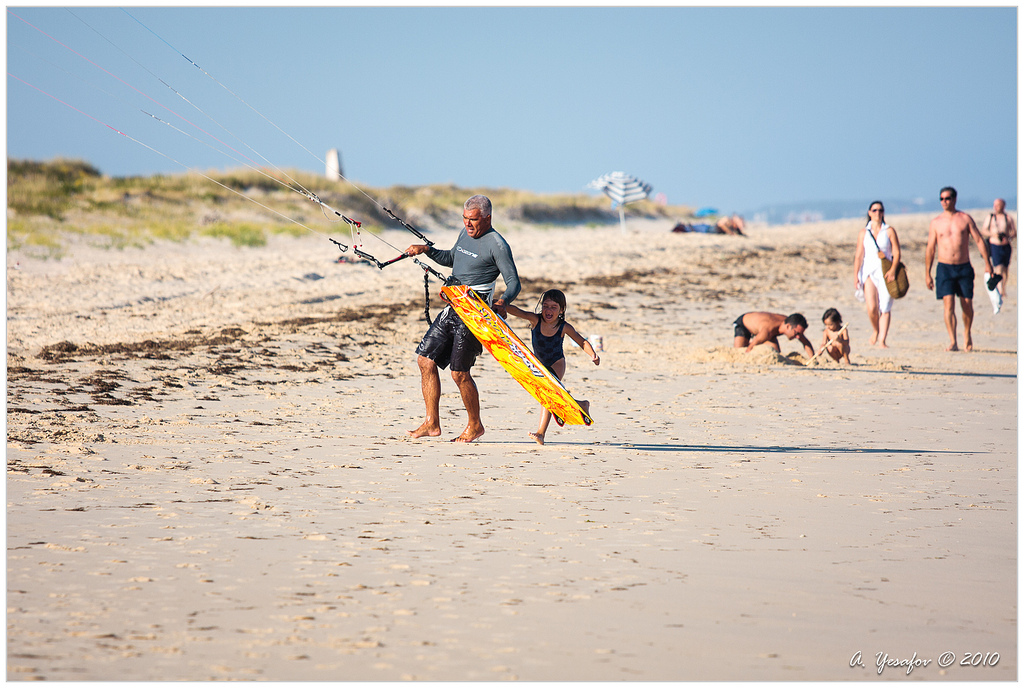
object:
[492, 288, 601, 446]
girl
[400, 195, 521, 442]
man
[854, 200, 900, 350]
woman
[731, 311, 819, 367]
man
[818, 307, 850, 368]
girl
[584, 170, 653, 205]
umbrella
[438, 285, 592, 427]
surfboard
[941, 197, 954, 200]
sunglasses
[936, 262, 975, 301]
pants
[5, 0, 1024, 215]
sky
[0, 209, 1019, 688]
sand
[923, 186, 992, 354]
people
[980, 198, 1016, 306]
people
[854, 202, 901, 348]
people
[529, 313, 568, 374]
swimsuit